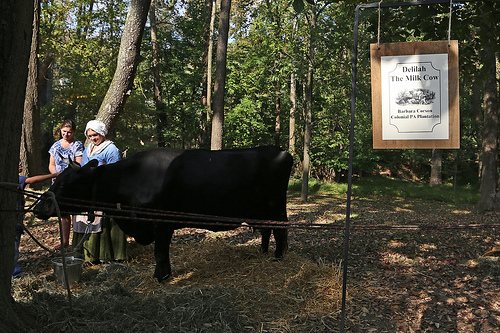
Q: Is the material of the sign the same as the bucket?
A: No, the sign is made of wood and the bucket is made of metal.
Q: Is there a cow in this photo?
A: Yes, there is a cow.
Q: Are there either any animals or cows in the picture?
A: Yes, there is a cow.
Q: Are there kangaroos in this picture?
A: No, there are no kangaroos.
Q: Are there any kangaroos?
A: No, there are no kangaroos.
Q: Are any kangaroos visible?
A: No, there are no kangaroos.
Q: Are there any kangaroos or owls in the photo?
A: No, there are no kangaroos or owls.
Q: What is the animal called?
A: The animal is a cow.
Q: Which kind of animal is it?
A: The animal is a cow.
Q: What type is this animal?
A: This is a cow.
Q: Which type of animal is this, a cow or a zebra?
A: This is a cow.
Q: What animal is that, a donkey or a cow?
A: That is a cow.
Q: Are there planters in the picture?
A: No, there are no planters.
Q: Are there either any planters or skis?
A: No, there are no planters or skis.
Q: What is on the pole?
A: The sign is on the pole.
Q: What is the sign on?
A: The sign is on the pole.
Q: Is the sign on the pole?
A: Yes, the sign is on the pole.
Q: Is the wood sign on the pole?
A: Yes, the sign is on the pole.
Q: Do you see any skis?
A: No, there are no skis.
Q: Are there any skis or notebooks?
A: No, there are no skis or notebooks.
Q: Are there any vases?
A: No, there are no vases.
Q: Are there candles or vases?
A: No, there are no vases or candles.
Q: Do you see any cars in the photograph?
A: No, there are no cars.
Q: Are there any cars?
A: No, there are no cars.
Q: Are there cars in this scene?
A: No, there are no cars.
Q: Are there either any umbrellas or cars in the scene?
A: No, there are no cars or umbrellas.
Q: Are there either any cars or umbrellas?
A: No, there are no cars or umbrellas.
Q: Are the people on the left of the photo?
A: Yes, the people are on the left of the image.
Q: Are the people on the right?
A: No, the people are on the left of the image.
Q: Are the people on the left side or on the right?
A: The people are on the left of the image.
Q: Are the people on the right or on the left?
A: The people are on the left of the image.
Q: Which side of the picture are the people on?
A: The people are on the left of the image.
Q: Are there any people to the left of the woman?
A: Yes, there are people to the left of the woman.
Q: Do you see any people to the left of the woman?
A: Yes, there are people to the left of the woman.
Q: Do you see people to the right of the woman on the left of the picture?
A: No, the people are to the left of the woman.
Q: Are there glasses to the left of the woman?
A: No, there are people to the left of the woman.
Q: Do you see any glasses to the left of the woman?
A: No, there are people to the left of the woman.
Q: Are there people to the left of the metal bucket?
A: Yes, there are people to the left of the bucket.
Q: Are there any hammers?
A: No, there are no hammers.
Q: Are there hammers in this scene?
A: No, there are no hammers.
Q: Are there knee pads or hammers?
A: No, there are no hammers or knee pads.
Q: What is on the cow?
A: The rope is on the cow.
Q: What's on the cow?
A: The rope is on the cow.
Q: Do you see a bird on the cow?
A: No, there is a rope on the cow.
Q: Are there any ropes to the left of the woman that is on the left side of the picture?
A: Yes, there is a rope to the left of the woman.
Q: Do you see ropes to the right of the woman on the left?
A: No, the rope is to the left of the woman.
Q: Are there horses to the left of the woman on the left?
A: No, there is a rope to the left of the woman.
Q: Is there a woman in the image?
A: Yes, there is a woman.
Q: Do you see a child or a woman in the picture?
A: Yes, there is a woman.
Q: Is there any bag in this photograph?
A: No, there are no bags.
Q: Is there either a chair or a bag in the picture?
A: No, there are no bags or chairs.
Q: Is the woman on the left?
A: Yes, the woman is on the left of the image.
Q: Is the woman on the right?
A: No, the woman is on the left of the image.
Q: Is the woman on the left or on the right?
A: The woman is on the left of the image.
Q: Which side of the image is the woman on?
A: The woman is on the left of the image.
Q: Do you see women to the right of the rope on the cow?
A: Yes, there is a woman to the right of the rope.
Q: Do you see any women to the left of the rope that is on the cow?
A: No, the woman is to the right of the rope.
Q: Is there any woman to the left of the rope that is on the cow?
A: No, the woman is to the right of the rope.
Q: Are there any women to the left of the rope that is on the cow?
A: No, the woman is to the right of the rope.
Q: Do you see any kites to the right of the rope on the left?
A: No, there is a woman to the right of the rope.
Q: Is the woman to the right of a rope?
A: Yes, the woman is to the right of a rope.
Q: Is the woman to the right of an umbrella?
A: No, the woman is to the right of a rope.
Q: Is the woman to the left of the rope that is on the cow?
A: No, the woman is to the right of the rope.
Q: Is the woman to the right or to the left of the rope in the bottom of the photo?
A: The woman is to the right of the rope.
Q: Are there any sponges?
A: No, there are no sponges.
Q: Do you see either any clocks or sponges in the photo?
A: No, there are no sponges or clocks.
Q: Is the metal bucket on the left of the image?
A: Yes, the bucket is on the left of the image.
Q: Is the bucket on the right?
A: No, the bucket is on the left of the image.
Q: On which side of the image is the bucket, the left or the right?
A: The bucket is on the left of the image.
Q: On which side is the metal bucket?
A: The bucket is on the left of the image.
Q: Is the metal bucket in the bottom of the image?
A: Yes, the bucket is in the bottom of the image.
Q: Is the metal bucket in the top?
A: No, the bucket is in the bottom of the image.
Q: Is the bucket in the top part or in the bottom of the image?
A: The bucket is in the bottom of the image.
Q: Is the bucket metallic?
A: Yes, the bucket is metallic.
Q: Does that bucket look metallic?
A: Yes, the bucket is metallic.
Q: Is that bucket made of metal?
A: Yes, the bucket is made of metal.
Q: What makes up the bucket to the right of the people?
A: The bucket is made of metal.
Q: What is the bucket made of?
A: The bucket is made of metal.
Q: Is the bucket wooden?
A: No, the bucket is metallic.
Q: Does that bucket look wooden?
A: No, the bucket is metallic.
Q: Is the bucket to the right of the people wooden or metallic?
A: The bucket is metallic.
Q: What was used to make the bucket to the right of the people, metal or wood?
A: The bucket is made of metal.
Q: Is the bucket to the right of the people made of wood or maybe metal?
A: The bucket is made of metal.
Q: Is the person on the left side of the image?
A: Yes, the person is on the left of the image.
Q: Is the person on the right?
A: No, the person is on the left of the image.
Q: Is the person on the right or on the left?
A: The person is on the left of the image.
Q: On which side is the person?
A: The person is on the left of the image.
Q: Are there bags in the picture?
A: No, there are no bags.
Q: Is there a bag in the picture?
A: No, there are no bags.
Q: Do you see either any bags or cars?
A: No, there are no bags or cars.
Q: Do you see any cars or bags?
A: No, there are no bags or cars.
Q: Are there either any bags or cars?
A: No, there are no bags or cars.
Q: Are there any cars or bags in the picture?
A: No, there are no bags or cars.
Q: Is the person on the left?
A: Yes, the person is on the left of the image.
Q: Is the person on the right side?
A: No, the person is on the left of the image.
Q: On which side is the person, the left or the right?
A: The person is on the left of the image.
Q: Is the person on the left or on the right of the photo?
A: The person is on the left of the image.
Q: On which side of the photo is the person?
A: The person is on the left of the image.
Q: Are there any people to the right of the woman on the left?
A: No, the person is to the left of the woman.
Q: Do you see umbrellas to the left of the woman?
A: No, there is a person to the left of the woman.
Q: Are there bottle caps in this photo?
A: No, there are no bottle caps.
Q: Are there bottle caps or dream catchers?
A: No, there are no bottle caps or dream catchers.